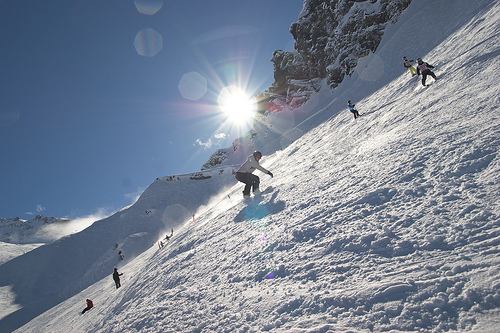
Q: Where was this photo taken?
A: On a ski slope.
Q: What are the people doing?
A: Snowboarding.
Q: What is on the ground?
A: Snow.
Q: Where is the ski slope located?
A: On a mountain.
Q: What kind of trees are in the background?
A: Pine trees.